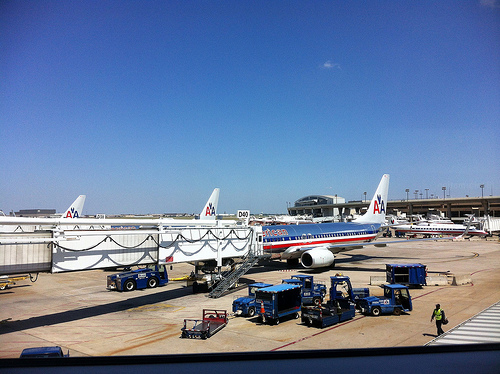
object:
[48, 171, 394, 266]
airplanes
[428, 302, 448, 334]
person is walking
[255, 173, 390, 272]
colored airplane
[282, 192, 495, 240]
building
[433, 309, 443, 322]
green vest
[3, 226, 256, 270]
an extension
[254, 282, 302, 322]
blue machine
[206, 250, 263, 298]
ladder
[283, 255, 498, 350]
passenger walkway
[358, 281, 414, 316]
transport truck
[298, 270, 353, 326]
blue vehicle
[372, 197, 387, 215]
aa on a plane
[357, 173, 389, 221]
plane tail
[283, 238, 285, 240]
window on plane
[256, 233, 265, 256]
exit door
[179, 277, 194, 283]
traffic cone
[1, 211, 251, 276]
white k-rail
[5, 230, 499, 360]
runway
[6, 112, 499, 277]
background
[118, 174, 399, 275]
planes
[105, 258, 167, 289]
machine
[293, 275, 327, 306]
machine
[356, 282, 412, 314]
machine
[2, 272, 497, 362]
runway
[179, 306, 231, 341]
machine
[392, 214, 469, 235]
airplane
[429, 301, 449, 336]
man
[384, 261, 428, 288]
luggage cart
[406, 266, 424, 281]
curtain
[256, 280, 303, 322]
luggage cart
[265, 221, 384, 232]
paint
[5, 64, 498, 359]
sunshine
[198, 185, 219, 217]
plane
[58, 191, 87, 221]
plane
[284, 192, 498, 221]
terminal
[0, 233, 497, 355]
cement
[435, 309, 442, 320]
vest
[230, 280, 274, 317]
vehicle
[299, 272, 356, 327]
vehicle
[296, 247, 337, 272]
engine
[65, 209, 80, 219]
aa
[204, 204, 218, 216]
aa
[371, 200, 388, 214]
aa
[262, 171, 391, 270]
plane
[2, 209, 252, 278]
ramp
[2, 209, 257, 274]
gate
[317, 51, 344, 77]
cloud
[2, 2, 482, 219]
sky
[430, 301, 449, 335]
airport worker